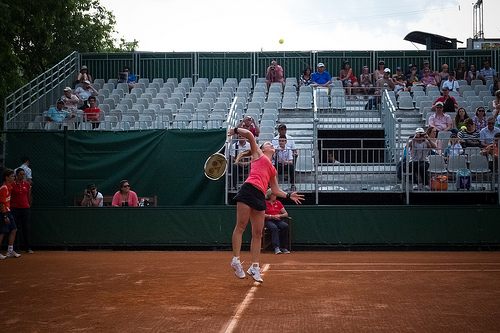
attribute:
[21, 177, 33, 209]
shirt — red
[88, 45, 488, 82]
fabric — opaque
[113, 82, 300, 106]
seats — empty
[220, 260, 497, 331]
lines — white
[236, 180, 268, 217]
skirt — black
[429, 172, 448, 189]
bag — light brown, small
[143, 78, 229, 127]
seats — empty, white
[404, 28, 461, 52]
slanted structure — dark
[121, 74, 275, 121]
chairs — empty, white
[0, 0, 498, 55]
sky — blue, clear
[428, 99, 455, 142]
people — disinterested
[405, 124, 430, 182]
people — disinterested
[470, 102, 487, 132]
people — disinterested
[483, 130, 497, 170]
people — disinterested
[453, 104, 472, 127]
people — disinterested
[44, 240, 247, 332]
court — brown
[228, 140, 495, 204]
railing — gray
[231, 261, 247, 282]
sneaker — white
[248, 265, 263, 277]
sneaker — white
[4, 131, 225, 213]
wall — green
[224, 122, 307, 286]
player — jumping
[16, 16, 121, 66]
tree — large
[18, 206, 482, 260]
partition — green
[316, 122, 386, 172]
passageway — dark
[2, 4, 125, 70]
tree — large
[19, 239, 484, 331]
court — clay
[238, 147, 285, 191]
top — pink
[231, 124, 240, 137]
arm band — black